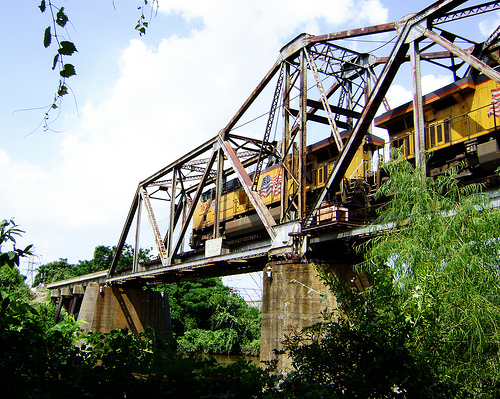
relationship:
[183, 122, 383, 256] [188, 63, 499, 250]
car on train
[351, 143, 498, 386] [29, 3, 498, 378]
tree by bridge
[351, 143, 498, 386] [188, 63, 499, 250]
tree by train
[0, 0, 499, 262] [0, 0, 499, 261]
cloud in sky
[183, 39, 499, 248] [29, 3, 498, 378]
train on bridge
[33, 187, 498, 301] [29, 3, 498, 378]
tracks on bridge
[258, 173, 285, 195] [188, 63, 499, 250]
flag on train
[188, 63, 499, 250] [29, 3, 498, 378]
train on bridge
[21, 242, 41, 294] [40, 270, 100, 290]
electric tower near bridge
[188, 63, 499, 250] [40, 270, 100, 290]
train on bridge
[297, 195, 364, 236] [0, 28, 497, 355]
platform on bridge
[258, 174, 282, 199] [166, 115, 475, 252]
flag on train